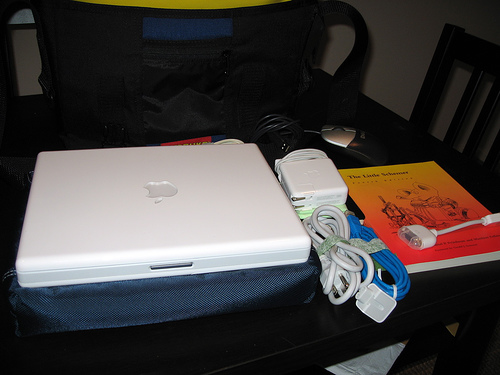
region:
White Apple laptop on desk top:
[13, 142, 311, 288]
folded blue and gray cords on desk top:
[301, 203, 411, 323]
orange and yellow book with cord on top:
[338, 159, 499, 272]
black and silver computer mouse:
[320, 120, 395, 165]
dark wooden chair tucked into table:
[404, 18, 499, 168]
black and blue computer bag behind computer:
[30, 0, 375, 147]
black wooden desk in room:
[0, 68, 499, 373]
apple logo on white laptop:
[142, 178, 179, 205]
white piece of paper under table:
[326, 340, 408, 374]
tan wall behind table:
[12, 28, 44, 96]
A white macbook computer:
[6, 136, 321, 288]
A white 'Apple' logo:
[131, 171, 182, 202]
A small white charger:
[390, 206, 497, 257]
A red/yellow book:
[335, 157, 495, 277]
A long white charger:
[300, 205, 395, 331]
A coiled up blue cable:
[340, 207, 416, 294]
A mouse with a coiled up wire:
[237, 97, 388, 159]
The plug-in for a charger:
[266, 137, 356, 207]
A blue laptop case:
[1, 185, 333, 336]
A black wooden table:
[0, 51, 497, 372]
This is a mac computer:
[74, 131, 386, 338]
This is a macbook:
[76, 143, 252, 268]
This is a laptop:
[38, 111, 286, 308]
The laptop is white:
[56, 181, 328, 296]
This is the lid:
[66, 206, 163, 223]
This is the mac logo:
[128, 139, 192, 226]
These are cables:
[298, 233, 418, 293]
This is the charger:
[274, 139, 337, 189]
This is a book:
[340, 157, 495, 293]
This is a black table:
[90, 72, 233, 153]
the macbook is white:
[16, 149, 293, 304]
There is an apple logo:
[140, 175, 187, 216]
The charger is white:
[276, 166, 383, 309]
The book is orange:
[334, 156, 498, 266]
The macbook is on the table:
[7, 129, 413, 351]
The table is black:
[16, 88, 366, 372]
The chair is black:
[398, 23, 494, 147]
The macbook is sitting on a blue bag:
[27, 183, 297, 355]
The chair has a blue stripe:
[136, 13, 241, 42]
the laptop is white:
[11, 127, 325, 303]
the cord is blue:
[353, 199, 412, 313]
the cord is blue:
[322, 140, 421, 335]